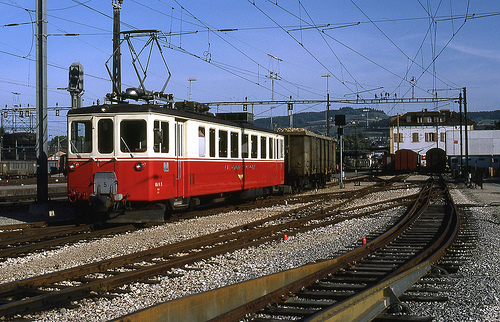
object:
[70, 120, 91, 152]
window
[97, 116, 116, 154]
window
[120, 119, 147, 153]
window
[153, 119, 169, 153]
window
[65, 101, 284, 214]
train car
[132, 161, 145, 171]
headlight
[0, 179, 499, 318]
gravel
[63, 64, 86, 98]
traffic lights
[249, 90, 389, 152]
ground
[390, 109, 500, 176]
building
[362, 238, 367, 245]
object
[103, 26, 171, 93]
black bar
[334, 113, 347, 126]
sign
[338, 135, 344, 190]
sign post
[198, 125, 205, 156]
window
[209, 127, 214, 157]
window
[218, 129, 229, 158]
window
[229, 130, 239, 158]
window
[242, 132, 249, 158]
window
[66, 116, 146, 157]
windows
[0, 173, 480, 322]
tracks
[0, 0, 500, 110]
power lines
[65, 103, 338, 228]
car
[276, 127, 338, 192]
train car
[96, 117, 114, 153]
door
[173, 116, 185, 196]
door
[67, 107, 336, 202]
train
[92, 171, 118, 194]
grey front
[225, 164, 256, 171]
writing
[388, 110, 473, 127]
roof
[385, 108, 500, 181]
house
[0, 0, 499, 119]
structures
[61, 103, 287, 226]
engine